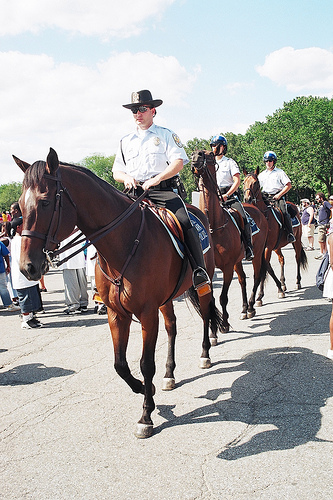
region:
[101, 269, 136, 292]
black strap around horse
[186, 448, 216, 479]
cracked line in the sidewalk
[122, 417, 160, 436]
gray color on horse's foot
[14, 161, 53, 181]
black hair in front of horse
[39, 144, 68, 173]
black ears on horse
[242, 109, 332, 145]
vibrant green trees in the background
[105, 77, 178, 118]
wide brimmed black hat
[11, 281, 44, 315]
boy wearing baggy jean pants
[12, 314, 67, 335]
black and white sneakers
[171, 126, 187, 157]
lapel on side of shirt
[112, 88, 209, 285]
Officer riding a horse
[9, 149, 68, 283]
The face of horse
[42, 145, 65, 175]
A horses left ear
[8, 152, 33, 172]
A horses right ear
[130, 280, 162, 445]
A horses left leg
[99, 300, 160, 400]
A horses right leg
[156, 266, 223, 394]
A horses back legs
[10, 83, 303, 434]
Cops riding many horses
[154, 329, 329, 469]
The shadow of a horse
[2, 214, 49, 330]
a man in white shirt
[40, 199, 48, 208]
The eye of the horse in the front.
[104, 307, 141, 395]
The front left leg of the horse in the front.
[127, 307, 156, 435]
The front right leg of the horse in the front.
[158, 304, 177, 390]
The back left leg of the horse in the front.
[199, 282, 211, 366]
The back right leg of the horse in the front.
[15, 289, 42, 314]
The blue jean shorts the guy is wearing.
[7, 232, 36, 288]
The white t-shirt the guy wearing the shorts has on.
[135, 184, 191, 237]
The saddle on the horse in the front.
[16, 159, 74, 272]
The harness the horse in the front has on.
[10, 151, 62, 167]
The ears of the horse in the front.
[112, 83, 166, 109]
the hat worn by the officer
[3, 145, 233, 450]
the horse in the front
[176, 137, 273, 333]
the horse in the middle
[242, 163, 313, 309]
the horse in the rear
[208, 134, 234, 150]
the helmet of the officer in the middle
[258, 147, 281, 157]
the helmet of the officer in the rear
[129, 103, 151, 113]
the sunglasses of the officer in the front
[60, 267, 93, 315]
the grey pants of a spectator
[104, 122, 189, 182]
the white shirt of the officer in front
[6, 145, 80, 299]
the head of the horse in front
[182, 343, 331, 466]
horse's shadow on the ground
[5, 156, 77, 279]
horse wearing a bridle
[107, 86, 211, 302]
policeman riding a horse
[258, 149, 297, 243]
policeman wearing a helmet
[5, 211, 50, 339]
child watching the policemen ride horses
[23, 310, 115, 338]
child's shadow on the ground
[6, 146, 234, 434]
a horse walking on the pavement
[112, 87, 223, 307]
policeman with his feet in the stirrups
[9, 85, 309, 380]
three policemen riding horses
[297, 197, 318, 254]
man in the crowd wearing a cap